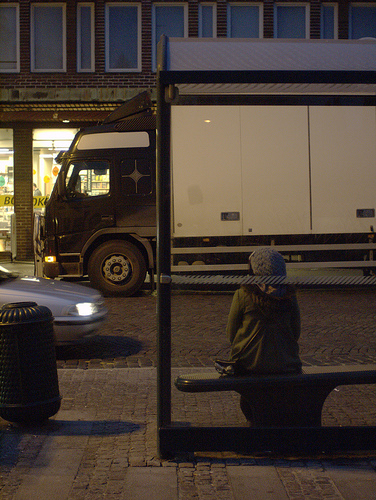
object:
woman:
[214, 246, 309, 378]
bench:
[174, 363, 376, 430]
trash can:
[0, 301, 61, 426]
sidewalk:
[5, 364, 373, 498]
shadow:
[8, 416, 153, 441]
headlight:
[74, 302, 98, 317]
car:
[0, 259, 108, 351]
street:
[1, 279, 374, 369]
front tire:
[83, 236, 148, 299]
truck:
[34, 68, 374, 297]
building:
[0, 0, 374, 260]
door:
[52, 159, 118, 241]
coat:
[212, 282, 303, 369]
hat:
[247, 245, 288, 287]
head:
[241, 247, 288, 293]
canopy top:
[160, 36, 375, 73]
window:
[68, 160, 111, 196]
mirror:
[57, 174, 64, 197]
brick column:
[12, 122, 34, 257]